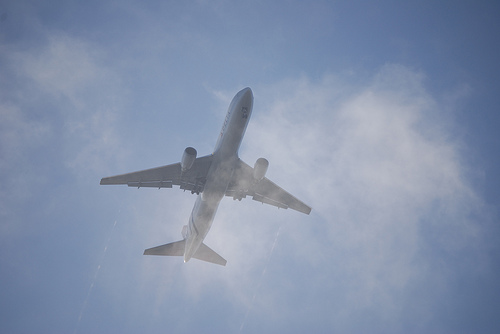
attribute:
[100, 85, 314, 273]
airplane — large, white, flying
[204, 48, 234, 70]
sky — blue